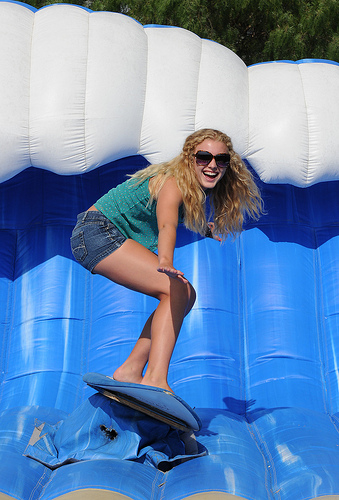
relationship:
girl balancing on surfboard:
[70, 129, 268, 397] [78, 358, 203, 437]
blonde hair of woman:
[126, 128, 269, 247] [115, 106, 264, 244]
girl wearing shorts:
[70, 129, 268, 397] [66, 206, 136, 267]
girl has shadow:
[70, 129, 268, 397] [189, 396, 293, 436]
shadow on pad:
[189, 396, 293, 436] [4, 17, 336, 498]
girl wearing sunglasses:
[70, 129, 268, 397] [188, 148, 230, 165]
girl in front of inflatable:
[70, 129, 268, 397] [2, 2, 332, 496]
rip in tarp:
[96, 421, 121, 443] [0, 1, 337, 496]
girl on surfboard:
[67, 126, 268, 397] [81, 370, 201, 431]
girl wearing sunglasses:
[70, 129, 268, 397] [193, 149, 232, 167]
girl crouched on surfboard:
[70, 129, 268, 397] [81, 370, 201, 431]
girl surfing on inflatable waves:
[70, 129, 268, 397] [1, 1, 335, 496]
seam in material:
[74, 22, 95, 164] [2, 33, 323, 159]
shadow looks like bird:
[189, 396, 293, 436] [222, 393, 257, 416]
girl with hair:
[70, 129, 268, 397] [220, 148, 264, 237]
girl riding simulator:
[70, 129, 268, 397] [21, 369, 208, 463]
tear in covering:
[94, 418, 119, 448] [2, 184, 338, 499]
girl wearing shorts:
[70, 129, 268, 397] [71, 214, 111, 264]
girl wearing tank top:
[70, 129, 268, 397] [93, 170, 157, 253]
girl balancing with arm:
[70, 129, 268, 397] [148, 185, 189, 287]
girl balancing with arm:
[70, 129, 268, 397] [187, 204, 229, 247]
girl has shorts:
[70, 129, 268, 397] [70, 210, 126, 274]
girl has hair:
[70, 129, 268, 397] [132, 118, 277, 250]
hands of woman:
[147, 213, 227, 285] [58, 124, 269, 284]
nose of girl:
[209, 158, 216, 169] [70, 129, 268, 397]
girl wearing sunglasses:
[70, 129, 268, 397] [189, 149, 230, 169]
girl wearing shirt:
[70, 129, 268, 397] [94, 169, 175, 253]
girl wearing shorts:
[70, 129, 268, 397] [70, 210, 126, 274]